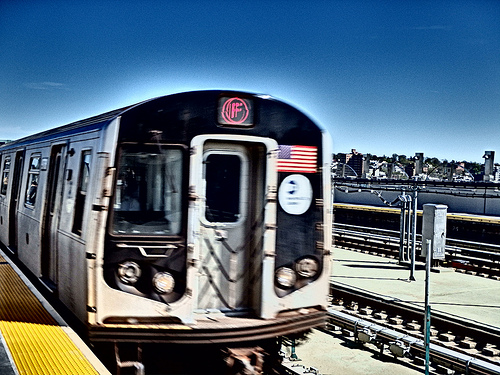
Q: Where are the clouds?
A: In the sky.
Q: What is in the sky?
A: Clouds.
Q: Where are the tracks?
A: Under the train.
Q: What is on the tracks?
A: The train.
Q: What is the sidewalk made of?
A: Cement.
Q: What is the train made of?
A: Metal.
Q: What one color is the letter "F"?
A: Red.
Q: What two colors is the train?
A: Black and white.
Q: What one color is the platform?
A: Yellow.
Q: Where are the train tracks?
A: Next to the train.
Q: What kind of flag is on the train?
A: American flag.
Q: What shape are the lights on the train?
A: Circle.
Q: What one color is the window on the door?
A: Black.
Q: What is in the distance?
A: Buildings.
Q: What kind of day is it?
A: A clear day.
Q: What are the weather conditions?
A: Clear blue skies.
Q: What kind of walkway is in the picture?
A: A yellow walkway.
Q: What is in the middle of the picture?
A: A train.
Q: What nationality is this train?
A: American.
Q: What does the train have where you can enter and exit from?
A: A door.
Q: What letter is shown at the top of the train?
A: F.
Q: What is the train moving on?
A: Rails.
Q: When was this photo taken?
A: In the middle of the day.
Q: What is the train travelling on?
A: Train tracks.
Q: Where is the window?
A: On the back.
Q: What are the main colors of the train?
A: Black and white.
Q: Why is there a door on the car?
A: To get in.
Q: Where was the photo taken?
A: Train yard.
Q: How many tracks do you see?
A: 3.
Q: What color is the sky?
A: Blue.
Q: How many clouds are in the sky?
A: 1.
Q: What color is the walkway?
A: Yellow.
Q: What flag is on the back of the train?
A: American.